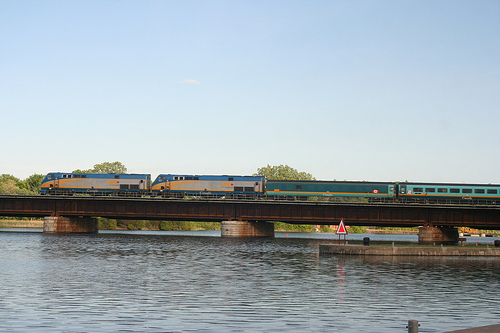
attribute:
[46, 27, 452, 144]
sky — clear, cloudless, blue, bright, planeless, distance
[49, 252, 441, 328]
water — calm, island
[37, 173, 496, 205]
train — blue, yellow, green, short, car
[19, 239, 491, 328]
river — calm, large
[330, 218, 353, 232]
sign — triangular, red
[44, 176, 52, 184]
pilot — eating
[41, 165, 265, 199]
engines — yellow, black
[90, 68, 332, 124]
clouds — white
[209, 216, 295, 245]
stumps — brick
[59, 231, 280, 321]
lake — brown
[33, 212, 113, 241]
pillars — stone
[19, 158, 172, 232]
trees — green